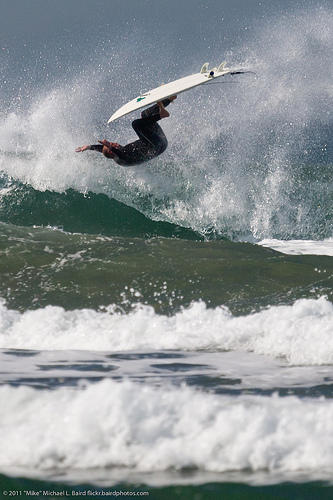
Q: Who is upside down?
A: Surfer.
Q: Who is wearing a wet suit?
A: Surfer.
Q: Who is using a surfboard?
A: Man in wetsuit.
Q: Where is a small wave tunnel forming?
A: Below the man.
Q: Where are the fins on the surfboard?
A: Pointed to the sky.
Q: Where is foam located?
A: Surface of water between two breaking waves.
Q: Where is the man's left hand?
A: Raised above the man's head pointing to your left.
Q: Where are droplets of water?
A: In the air above the surfer.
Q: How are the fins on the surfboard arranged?
A: In a triangle.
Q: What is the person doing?
A: Surfing.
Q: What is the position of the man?
A: Upside down.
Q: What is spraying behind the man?
A: Water.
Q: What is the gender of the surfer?
A: Male.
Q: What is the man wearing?
A: Wetsuit.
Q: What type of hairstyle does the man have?
A: He is bald.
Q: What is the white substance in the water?
A: Foam.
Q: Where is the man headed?
A: Into the water.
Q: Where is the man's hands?
A: Over his head.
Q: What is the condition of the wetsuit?
A: It is wet.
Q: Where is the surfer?
A: Under the surfboard.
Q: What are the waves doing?
A: Crashing in the ocean.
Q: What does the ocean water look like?
A: Green and blue.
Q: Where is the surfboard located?
A: Over the man.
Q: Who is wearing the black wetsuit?
A: The man.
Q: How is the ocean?
A: Wavy.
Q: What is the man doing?
A: Surfing.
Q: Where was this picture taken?
A: In the ocean.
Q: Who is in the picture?
A: A surfer.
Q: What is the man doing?
A: Surfing.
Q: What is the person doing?
A: Surfing.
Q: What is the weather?
A: Sunny.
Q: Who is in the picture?
A: A surfer.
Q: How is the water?
A: Choppy.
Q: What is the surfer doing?
A: Surfing.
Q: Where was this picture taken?
A: An ocean.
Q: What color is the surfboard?
A: White.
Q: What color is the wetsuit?
A: Black.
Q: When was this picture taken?
A: Daytime.